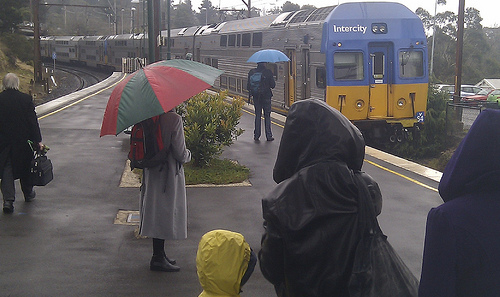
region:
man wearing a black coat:
[0, 65, 62, 217]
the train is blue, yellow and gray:
[7, 3, 448, 141]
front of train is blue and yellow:
[323, 0, 438, 141]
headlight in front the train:
[354, 95, 411, 114]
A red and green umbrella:
[86, 53, 225, 138]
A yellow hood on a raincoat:
[192, 230, 255, 295]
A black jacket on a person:
[264, 99, 369, 294]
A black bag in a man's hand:
[24, 150, 54, 183]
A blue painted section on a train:
[328, 3, 428, 81]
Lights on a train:
[365, 18, 395, 40]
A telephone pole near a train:
[453, 0, 465, 123]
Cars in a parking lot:
[442, 83, 497, 100]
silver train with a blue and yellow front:
[24, 5, 433, 141]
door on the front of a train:
[363, 38, 397, 123]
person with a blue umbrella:
[240, 43, 282, 149]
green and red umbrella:
[94, 49, 227, 146]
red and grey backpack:
[128, 108, 168, 175]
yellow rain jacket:
[188, 222, 250, 295]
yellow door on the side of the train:
[284, 45, 297, 110]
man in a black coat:
[1, 65, 51, 212]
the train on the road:
[1, 0, 498, 154]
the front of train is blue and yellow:
[317, 0, 434, 133]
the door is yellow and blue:
[359, 34, 399, 122]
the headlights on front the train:
[351, 92, 409, 116]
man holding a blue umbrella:
[240, 40, 290, 147]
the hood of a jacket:
[179, 216, 261, 294]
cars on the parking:
[433, 69, 498, 111]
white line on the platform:
[366, 143, 440, 199]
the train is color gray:
[16, 0, 443, 133]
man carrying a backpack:
[236, 45, 281, 148]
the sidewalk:
[59, 241, 114, 280]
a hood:
[195, 231, 243, 287]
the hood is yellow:
[198, 233, 238, 286]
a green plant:
[196, 97, 233, 152]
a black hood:
[292, 103, 344, 154]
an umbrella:
[112, 61, 201, 109]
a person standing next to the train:
[246, 64, 284, 141]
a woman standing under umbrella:
[95, 56, 222, 272]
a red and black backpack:
[127, 117, 164, 171]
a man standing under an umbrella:
[245, 47, 290, 141]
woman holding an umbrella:
[92, 46, 225, 271]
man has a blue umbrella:
[242, 41, 289, 150]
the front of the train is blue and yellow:
[321, 2, 437, 126]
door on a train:
[365, 32, 392, 122]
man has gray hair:
[1, 64, 58, 222]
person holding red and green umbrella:
[95, 57, 224, 275]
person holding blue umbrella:
[245, 46, 290, 144]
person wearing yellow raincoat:
[193, 228, 257, 294]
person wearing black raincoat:
[257, 97, 381, 294]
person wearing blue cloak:
[417, 101, 498, 291]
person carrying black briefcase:
[1, 70, 55, 212]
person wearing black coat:
[0, 72, 42, 216]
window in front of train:
[335, 51, 366, 83]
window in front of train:
[401, 49, 425, 77]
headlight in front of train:
[355, 99, 366, 110]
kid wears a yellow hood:
[184, 220, 261, 296]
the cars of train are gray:
[16, 1, 437, 97]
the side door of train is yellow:
[278, 44, 301, 108]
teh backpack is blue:
[244, 65, 265, 99]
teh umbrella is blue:
[243, 44, 292, 66]